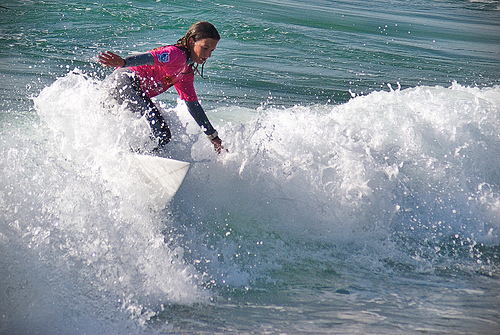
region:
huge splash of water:
[278, 121, 460, 331]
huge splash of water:
[248, 67, 426, 291]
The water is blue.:
[268, 4, 425, 67]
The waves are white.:
[252, 100, 498, 250]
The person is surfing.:
[55, 15, 247, 235]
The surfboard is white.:
[46, 120, 208, 222]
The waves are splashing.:
[261, 105, 498, 242]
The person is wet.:
[45, 17, 249, 212]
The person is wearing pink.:
[67, 10, 247, 215]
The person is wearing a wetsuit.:
[62, 17, 239, 213]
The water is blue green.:
[257, 5, 433, 65]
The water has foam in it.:
[207, 225, 498, 333]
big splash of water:
[275, 112, 400, 229]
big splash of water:
[278, 41, 463, 216]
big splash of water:
[277, 101, 435, 295]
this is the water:
[301, 2, 484, 59]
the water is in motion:
[316, 2, 449, 43]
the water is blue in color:
[302, 0, 471, 57]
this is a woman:
[83, 22, 243, 154]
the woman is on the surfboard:
[82, 26, 228, 151]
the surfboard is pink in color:
[138, 66, 169, 74]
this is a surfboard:
[126, 150, 190, 187]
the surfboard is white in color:
[151, 165, 177, 190]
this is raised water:
[366, 94, 494, 178]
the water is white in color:
[54, 222, 106, 267]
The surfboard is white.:
[126, 146, 201, 210]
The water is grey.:
[341, 278, 496, 333]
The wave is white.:
[33, 85, 161, 272]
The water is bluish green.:
[249, 7, 403, 82]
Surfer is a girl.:
[79, 20, 243, 216]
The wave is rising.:
[276, 154, 446, 227]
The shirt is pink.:
[143, 34, 198, 111]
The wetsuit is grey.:
[87, 43, 221, 162]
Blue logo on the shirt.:
[150, 41, 180, 74]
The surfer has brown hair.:
[178, 14, 225, 64]